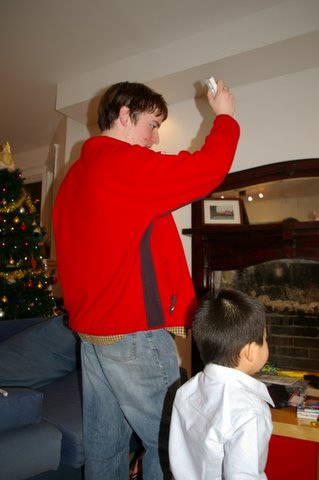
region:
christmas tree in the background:
[0, 140, 61, 323]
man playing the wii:
[53, 74, 238, 475]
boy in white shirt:
[166, 283, 276, 475]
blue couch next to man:
[0, 314, 90, 475]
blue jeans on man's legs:
[79, 329, 186, 478]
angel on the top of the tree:
[0, 140, 19, 173]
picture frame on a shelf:
[201, 195, 242, 223]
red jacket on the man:
[49, 114, 239, 332]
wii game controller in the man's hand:
[205, 77, 218, 94]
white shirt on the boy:
[167, 362, 274, 475]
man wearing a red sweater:
[63, 168, 132, 270]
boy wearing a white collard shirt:
[193, 382, 251, 450]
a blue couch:
[18, 335, 74, 381]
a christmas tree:
[7, 229, 47, 301]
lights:
[244, 189, 272, 205]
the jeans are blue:
[83, 352, 138, 456]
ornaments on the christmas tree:
[7, 258, 44, 290]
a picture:
[203, 202, 242, 225]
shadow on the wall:
[189, 127, 211, 148]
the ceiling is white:
[73, 9, 173, 55]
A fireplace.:
[208, 250, 315, 376]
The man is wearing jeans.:
[65, 328, 195, 474]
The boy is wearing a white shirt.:
[155, 360, 284, 475]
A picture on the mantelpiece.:
[193, 185, 245, 230]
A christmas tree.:
[0, 121, 61, 338]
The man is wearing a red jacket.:
[31, 102, 238, 331]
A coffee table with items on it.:
[260, 353, 317, 446]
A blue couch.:
[0, 324, 81, 475]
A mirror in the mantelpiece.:
[235, 154, 316, 226]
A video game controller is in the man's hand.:
[190, 62, 263, 139]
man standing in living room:
[56, 76, 238, 476]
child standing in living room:
[167, 290, 271, 478]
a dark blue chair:
[0, 312, 77, 479]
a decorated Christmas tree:
[1, 142, 58, 313]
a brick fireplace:
[206, 255, 317, 373]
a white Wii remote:
[201, 73, 218, 97]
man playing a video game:
[50, 72, 239, 478]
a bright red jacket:
[52, 115, 238, 332]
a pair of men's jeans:
[79, 334, 181, 478]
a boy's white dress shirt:
[169, 365, 274, 478]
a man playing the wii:
[14, 24, 317, 299]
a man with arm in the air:
[65, 62, 245, 343]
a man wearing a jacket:
[13, 50, 272, 344]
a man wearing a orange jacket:
[23, 81, 262, 346]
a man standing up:
[42, 63, 197, 475]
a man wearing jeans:
[40, 84, 171, 475]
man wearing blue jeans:
[17, 74, 256, 477]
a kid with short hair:
[139, 289, 316, 464]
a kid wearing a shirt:
[131, 277, 295, 477]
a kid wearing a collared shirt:
[166, 287, 285, 479]